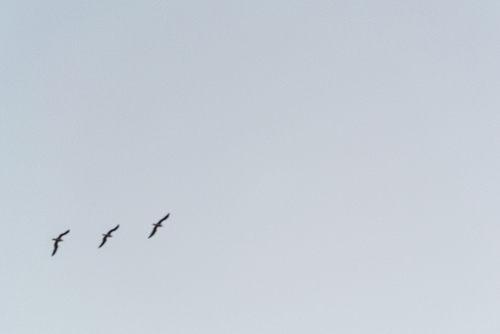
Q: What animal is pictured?
A: Birds.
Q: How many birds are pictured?
A: 3.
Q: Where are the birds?
A: In the sky.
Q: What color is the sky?
A: Gray.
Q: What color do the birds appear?
A: Black.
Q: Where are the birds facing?
A: Right.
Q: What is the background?
A: The sky.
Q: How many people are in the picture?
A: Zero.